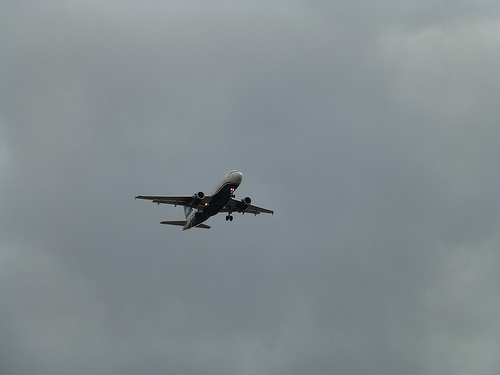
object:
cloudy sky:
[0, 1, 499, 374]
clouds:
[0, 0, 499, 375]